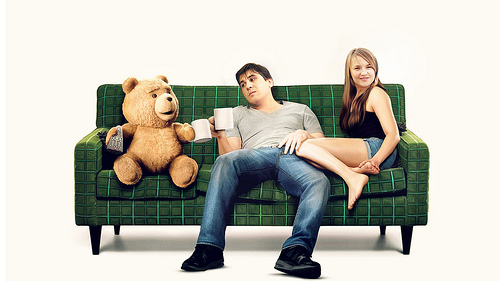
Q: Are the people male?
A: No, they are both male and female.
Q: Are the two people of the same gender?
A: No, they are both male and female.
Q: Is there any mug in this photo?
A: Yes, there is a mug.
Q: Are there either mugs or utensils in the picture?
A: Yes, there is a mug.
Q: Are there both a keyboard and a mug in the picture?
A: No, there is a mug but no keyboards.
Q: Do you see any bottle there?
A: No, there are no bottles.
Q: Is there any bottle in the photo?
A: No, there are no bottles.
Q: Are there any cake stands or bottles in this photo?
A: No, there are no bottles or cake stands.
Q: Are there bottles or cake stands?
A: No, there are no bottles or cake stands.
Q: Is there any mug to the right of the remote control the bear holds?
A: Yes, there is a mug to the right of the remote control.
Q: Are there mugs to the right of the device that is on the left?
A: Yes, there is a mug to the right of the remote control.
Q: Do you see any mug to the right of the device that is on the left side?
A: Yes, there is a mug to the right of the remote control.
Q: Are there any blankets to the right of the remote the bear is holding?
A: No, there is a mug to the right of the remote.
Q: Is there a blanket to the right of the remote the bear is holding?
A: No, there is a mug to the right of the remote.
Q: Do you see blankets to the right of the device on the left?
A: No, there is a mug to the right of the remote.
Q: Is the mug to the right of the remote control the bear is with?
A: Yes, the mug is to the right of the remote.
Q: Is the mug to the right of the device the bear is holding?
A: Yes, the mug is to the right of the remote.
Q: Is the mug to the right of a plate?
A: No, the mug is to the right of the remote.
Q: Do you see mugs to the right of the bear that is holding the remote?
A: Yes, there is a mug to the right of the bear.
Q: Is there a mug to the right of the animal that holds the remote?
A: Yes, there is a mug to the right of the bear.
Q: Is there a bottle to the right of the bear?
A: No, there is a mug to the right of the bear.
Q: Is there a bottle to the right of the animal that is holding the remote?
A: No, there is a mug to the right of the bear.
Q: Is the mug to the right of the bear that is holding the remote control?
A: Yes, the mug is to the right of the bear.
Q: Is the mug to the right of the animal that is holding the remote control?
A: Yes, the mug is to the right of the bear.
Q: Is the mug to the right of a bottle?
A: No, the mug is to the right of the bear.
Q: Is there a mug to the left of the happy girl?
A: Yes, there is a mug to the left of the girl.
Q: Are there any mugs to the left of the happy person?
A: Yes, there is a mug to the left of the girl.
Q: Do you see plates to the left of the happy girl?
A: No, there is a mug to the left of the girl.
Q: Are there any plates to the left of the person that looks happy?
A: No, there is a mug to the left of the girl.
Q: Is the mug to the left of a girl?
A: Yes, the mug is to the left of a girl.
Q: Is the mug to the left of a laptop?
A: No, the mug is to the left of a girl.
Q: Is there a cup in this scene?
A: Yes, there is a cup.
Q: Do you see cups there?
A: Yes, there is a cup.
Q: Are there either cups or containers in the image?
A: Yes, there is a cup.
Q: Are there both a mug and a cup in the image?
A: Yes, there are both a cup and a mug.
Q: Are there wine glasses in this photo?
A: No, there are no wine glasses.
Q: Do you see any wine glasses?
A: No, there are no wine glasses.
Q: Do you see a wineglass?
A: No, there are no wine glasses.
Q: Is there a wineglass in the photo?
A: No, there are no wine glasses.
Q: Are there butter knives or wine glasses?
A: No, there are no wine glasses or butter knives.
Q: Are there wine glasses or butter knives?
A: No, there are no wine glasses or butter knives.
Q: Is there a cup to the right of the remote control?
A: Yes, there is a cup to the right of the remote control.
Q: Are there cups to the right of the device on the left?
A: Yes, there is a cup to the right of the remote control.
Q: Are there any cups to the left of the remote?
A: No, the cup is to the right of the remote.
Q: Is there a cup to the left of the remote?
A: No, the cup is to the right of the remote.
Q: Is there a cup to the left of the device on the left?
A: No, the cup is to the right of the remote.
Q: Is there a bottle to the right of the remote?
A: No, there is a cup to the right of the remote.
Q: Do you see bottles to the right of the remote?
A: No, there is a cup to the right of the remote.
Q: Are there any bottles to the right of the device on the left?
A: No, there is a cup to the right of the remote.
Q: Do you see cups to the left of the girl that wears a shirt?
A: Yes, there is a cup to the left of the girl.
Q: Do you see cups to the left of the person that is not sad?
A: Yes, there is a cup to the left of the girl.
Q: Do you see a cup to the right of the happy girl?
A: No, the cup is to the left of the girl.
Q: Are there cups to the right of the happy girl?
A: No, the cup is to the left of the girl.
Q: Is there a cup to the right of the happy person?
A: No, the cup is to the left of the girl.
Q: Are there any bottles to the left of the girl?
A: No, there is a cup to the left of the girl.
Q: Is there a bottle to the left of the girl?
A: No, there is a cup to the left of the girl.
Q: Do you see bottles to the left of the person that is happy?
A: No, there is a cup to the left of the girl.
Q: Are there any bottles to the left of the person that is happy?
A: No, there is a cup to the left of the girl.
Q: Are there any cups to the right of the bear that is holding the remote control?
A: Yes, there is a cup to the right of the bear.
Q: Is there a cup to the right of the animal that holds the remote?
A: Yes, there is a cup to the right of the bear.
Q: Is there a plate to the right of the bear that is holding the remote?
A: No, there is a cup to the right of the bear.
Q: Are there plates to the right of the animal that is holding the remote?
A: No, there is a cup to the right of the bear.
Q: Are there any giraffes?
A: No, there are no giraffes.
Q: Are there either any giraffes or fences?
A: No, there are no giraffes or fences.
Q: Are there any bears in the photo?
A: Yes, there is a bear.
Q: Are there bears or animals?
A: Yes, there is a bear.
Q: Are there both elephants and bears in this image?
A: No, there is a bear but no elephants.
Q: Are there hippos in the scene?
A: No, there are no hippos.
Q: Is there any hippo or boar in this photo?
A: No, there are no hippos or boars.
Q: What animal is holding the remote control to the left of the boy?
A: The bear is holding the remote control.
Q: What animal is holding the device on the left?
A: The bear is holding the remote control.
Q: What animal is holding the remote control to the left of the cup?
A: The animal is a bear.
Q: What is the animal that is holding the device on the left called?
A: The animal is a bear.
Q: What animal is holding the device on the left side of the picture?
A: The animal is a bear.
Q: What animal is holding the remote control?
A: The animal is a bear.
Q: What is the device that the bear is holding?
A: The device is a remote control.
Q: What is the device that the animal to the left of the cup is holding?
A: The device is a remote control.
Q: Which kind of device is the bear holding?
A: The bear is holding the remote control.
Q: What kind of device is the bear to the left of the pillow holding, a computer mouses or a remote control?
A: The bear is holding a remote control.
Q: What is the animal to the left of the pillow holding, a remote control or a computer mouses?
A: The bear is holding a remote control.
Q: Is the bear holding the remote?
A: Yes, the bear is holding the remote.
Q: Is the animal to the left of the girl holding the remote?
A: Yes, the bear is holding the remote.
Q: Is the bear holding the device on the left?
A: Yes, the bear is holding the remote.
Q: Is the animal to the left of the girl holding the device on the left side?
A: Yes, the bear is holding the remote.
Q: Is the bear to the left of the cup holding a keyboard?
A: No, the bear is holding the remote.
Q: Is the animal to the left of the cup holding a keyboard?
A: No, the bear is holding the remote.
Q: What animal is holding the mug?
A: The bear is holding the mug.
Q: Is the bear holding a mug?
A: Yes, the bear is holding a mug.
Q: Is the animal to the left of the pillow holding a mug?
A: Yes, the bear is holding a mug.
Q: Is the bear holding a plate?
A: No, the bear is holding a mug.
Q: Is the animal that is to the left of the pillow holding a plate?
A: No, the bear is holding a mug.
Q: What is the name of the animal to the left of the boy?
A: The animal is a bear.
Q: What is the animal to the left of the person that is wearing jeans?
A: The animal is a bear.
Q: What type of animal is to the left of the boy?
A: The animal is a bear.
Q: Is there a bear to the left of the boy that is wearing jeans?
A: Yes, there is a bear to the left of the boy.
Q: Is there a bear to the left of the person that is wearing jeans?
A: Yes, there is a bear to the left of the boy.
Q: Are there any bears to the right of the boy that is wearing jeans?
A: No, the bear is to the left of the boy.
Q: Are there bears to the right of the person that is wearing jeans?
A: No, the bear is to the left of the boy.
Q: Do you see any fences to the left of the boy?
A: No, there is a bear to the left of the boy.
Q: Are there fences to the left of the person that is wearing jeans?
A: No, there is a bear to the left of the boy.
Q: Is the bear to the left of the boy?
A: Yes, the bear is to the left of the boy.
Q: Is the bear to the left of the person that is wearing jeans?
A: Yes, the bear is to the left of the boy.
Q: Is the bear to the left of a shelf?
A: No, the bear is to the left of the boy.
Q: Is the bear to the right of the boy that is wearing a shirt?
A: No, the bear is to the left of the boy.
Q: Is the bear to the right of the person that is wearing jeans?
A: No, the bear is to the left of the boy.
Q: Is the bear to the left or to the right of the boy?
A: The bear is to the left of the boy.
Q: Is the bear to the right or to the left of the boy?
A: The bear is to the left of the boy.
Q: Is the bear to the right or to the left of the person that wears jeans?
A: The bear is to the left of the boy.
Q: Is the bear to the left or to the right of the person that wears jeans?
A: The bear is to the left of the boy.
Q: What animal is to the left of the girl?
A: The animal is a bear.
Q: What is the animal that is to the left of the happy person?
A: The animal is a bear.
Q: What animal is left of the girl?
A: The animal is a bear.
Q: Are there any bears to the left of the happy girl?
A: Yes, there is a bear to the left of the girl.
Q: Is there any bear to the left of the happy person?
A: Yes, there is a bear to the left of the girl.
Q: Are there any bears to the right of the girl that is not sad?
A: No, the bear is to the left of the girl.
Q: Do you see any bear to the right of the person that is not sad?
A: No, the bear is to the left of the girl.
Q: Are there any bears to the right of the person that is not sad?
A: No, the bear is to the left of the girl.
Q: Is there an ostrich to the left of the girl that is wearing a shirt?
A: No, there is a bear to the left of the girl.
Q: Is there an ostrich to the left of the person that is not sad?
A: No, there is a bear to the left of the girl.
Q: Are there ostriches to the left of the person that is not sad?
A: No, there is a bear to the left of the girl.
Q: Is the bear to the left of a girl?
A: Yes, the bear is to the left of a girl.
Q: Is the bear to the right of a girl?
A: No, the bear is to the left of a girl.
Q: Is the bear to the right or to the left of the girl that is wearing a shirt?
A: The bear is to the left of the girl.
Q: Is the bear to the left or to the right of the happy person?
A: The bear is to the left of the girl.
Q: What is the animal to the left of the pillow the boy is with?
A: The animal is a bear.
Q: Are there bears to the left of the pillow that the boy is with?
A: Yes, there is a bear to the left of the pillow.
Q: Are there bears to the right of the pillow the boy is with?
A: No, the bear is to the left of the pillow.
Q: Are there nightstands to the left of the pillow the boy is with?
A: No, there is a bear to the left of the pillow.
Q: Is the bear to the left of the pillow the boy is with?
A: Yes, the bear is to the left of the pillow.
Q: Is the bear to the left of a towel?
A: No, the bear is to the left of the pillow.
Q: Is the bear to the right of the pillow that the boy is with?
A: No, the bear is to the left of the pillow.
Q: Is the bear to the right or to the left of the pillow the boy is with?
A: The bear is to the left of the pillow.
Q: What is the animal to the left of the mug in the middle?
A: The animal is a bear.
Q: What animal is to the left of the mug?
A: The animal is a bear.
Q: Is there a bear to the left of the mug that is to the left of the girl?
A: Yes, there is a bear to the left of the mug.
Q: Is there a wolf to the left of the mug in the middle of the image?
A: No, there is a bear to the left of the mug.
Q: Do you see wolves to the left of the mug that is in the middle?
A: No, there is a bear to the left of the mug.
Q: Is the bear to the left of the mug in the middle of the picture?
A: Yes, the bear is to the left of the mug.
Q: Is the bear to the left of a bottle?
A: No, the bear is to the left of the mug.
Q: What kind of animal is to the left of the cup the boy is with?
A: The animal is a bear.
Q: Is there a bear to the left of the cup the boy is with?
A: Yes, there is a bear to the left of the cup.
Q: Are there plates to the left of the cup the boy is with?
A: No, there is a bear to the left of the cup.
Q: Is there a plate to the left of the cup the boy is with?
A: No, there is a bear to the left of the cup.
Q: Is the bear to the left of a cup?
A: Yes, the bear is to the left of a cup.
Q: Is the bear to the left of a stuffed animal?
A: No, the bear is to the left of a cup.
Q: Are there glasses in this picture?
A: No, there are no glasses.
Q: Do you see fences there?
A: No, there are no fences.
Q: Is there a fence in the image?
A: No, there are no fences.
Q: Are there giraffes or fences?
A: No, there are no fences or giraffes.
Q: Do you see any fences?
A: No, there are no fences.